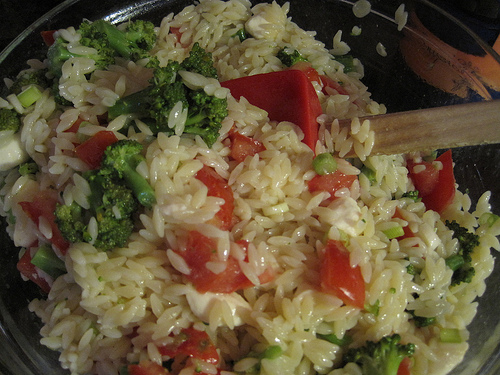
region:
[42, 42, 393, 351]
rice in a bowl with broccoli and peppers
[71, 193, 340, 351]
rice in a bowl with broccoli and peppers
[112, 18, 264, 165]
rice in a bowl with broccoli and peppers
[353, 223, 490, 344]
rice in a bowl with broccoli and peppers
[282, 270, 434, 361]
rice in a bowl with broccoli and peppers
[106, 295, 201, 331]
rice in a bowl with broccoli and peppers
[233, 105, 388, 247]
rice in a bowl with broccoli and peppers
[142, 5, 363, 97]
rice in a bowl with broccoli and peppers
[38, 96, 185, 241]
rice in a bowl with broccoli and peppers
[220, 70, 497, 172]
A spatula in the rice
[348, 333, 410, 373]
A piece of broccoli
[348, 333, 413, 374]
The broccoli is green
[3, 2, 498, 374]
A glass bowl full of a rice dish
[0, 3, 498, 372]
Rice in the glass bowl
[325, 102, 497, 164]
The handle on the spatula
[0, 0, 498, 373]
The bowl is made of glass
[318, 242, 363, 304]
A sliced tomato next to the rice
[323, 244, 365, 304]
The slice of tomato is red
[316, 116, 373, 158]
Rice on top of the spatula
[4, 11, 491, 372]
the food is in close up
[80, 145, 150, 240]
the food contains broccoli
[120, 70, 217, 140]
the food contains broccoli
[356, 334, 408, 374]
the food contains broccoli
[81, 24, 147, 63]
the food contains broccoli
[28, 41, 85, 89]
the food contains broccoli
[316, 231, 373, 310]
the food contains tomato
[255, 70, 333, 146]
the food contains tomato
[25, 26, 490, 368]
the food contains rice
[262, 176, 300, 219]
Grains of rice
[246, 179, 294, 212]
White rice grains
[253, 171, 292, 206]
Reflection on rice grains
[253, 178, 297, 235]
Cooked rice on a plate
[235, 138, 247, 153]
A piece of tomato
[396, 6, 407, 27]
Two grains of rice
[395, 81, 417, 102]
Surface of a transparent glass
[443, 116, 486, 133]
A wooden handle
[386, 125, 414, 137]
Wet smear on wooden handle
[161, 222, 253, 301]
tomato in the rice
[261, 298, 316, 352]
the rice is wet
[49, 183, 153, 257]
broccoli on the rice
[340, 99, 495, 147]
the spoon is wooden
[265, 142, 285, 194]
rice on the bowl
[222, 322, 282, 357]
peppers in the rice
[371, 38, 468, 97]
rim of the bowl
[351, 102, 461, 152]
handle of the spoon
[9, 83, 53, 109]
celery in the rice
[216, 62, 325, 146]
tomato in the rice